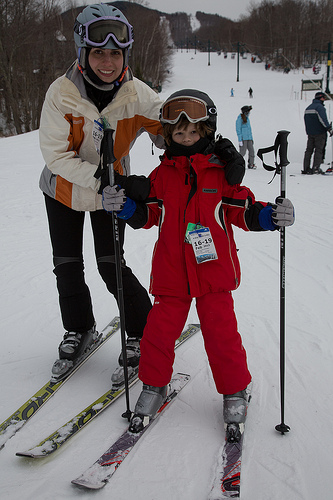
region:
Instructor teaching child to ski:
[4, 3, 296, 495]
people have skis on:
[1, 299, 253, 498]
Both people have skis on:
[52, 3, 230, 164]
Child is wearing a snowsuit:
[100, 87, 292, 454]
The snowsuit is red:
[107, 140, 279, 394]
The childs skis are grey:
[75, 367, 252, 495]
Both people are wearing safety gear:
[67, 2, 222, 157]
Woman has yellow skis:
[0, 314, 209, 464]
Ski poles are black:
[98, 123, 296, 439]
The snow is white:
[0, 43, 331, 498]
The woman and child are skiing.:
[50, 23, 279, 488]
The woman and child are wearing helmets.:
[64, 1, 218, 164]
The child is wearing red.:
[124, 106, 261, 409]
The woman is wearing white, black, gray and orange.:
[36, 60, 139, 320]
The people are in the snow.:
[32, 218, 295, 490]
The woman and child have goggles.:
[59, 22, 207, 146]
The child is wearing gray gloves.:
[93, 183, 294, 235]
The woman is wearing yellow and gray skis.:
[0, 319, 100, 454]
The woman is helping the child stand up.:
[86, 100, 223, 245]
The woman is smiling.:
[66, 6, 129, 81]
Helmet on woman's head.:
[72, 2, 135, 90]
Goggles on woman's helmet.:
[71, 14, 135, 47]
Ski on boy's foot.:
[205, 384, 253, 498]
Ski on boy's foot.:
[69, 371, 193, 490]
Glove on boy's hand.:
[255, 196, 297, 233]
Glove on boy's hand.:
[100, 182, 138, 221]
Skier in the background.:
[246, 85, 256, 98]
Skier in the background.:
[227, 85, 236, 98]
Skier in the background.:
[232, 102, 260, 171]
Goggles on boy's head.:
[157, 92, 218, 128]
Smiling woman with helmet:
[57, 5, 152, 91]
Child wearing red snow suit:
[136, 86, 264, 327]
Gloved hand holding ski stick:
[243, 172, 317, 242]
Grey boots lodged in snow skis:
[117, 362, 277, 449]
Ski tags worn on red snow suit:
[172, 211, 248, 270]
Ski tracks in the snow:
[245, 302, 328, 395]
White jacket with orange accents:
[16, 69, 174, 213]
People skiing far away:
[220, 80, 267, 102]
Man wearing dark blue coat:
[290, 88, 331, 174]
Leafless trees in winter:
[238, 0, 324, 71]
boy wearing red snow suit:
[145, 83, 288, 479]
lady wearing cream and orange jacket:
[26, 4, 202, 261]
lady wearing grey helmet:
[58, 0, 174, 86]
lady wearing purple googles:
[73, 14, 143, 52]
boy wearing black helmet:
[157, 81, 232, 154]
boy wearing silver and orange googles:
[152, 91, 223, 135]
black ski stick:
[240, 111, 306, 451]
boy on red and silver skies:
[54, 354, 315, 495]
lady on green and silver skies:
[8, 302, 207, 473]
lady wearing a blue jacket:
[224, 98, 291, 190]